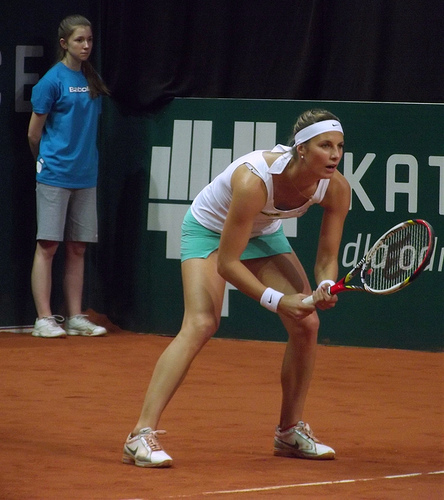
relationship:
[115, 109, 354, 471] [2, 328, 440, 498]
woman playing on court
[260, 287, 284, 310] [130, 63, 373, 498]
wrist band on woman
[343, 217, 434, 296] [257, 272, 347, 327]
racket in hands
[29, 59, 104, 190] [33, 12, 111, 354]
shirt on woman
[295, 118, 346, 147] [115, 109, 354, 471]
headband on woman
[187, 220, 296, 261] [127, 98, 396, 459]
tennis uniform on woman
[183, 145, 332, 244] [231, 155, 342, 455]
tank on body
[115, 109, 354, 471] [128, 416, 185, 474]
woman wearing shoe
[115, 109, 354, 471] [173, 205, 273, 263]
woman wearing skirt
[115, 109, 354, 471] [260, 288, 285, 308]
woman wearing band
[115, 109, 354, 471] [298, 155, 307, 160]
woman wearing earring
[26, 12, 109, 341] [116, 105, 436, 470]
girl standing behind tennis player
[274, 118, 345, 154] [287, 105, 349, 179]
headband on head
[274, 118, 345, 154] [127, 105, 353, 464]
headband on woman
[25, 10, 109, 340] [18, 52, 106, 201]
woman wearing a shirt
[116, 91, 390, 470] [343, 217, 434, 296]
woman holding racket